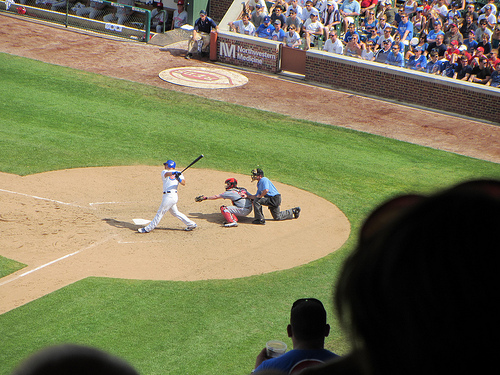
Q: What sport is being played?
A: Baseball.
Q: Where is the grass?
A: On the field.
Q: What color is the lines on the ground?
A: White.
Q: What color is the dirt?
A: Brown.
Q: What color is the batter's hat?
A: Blue.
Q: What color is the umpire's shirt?
A: Light blue.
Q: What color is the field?
A: Green and brown.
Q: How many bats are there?
A: 1.